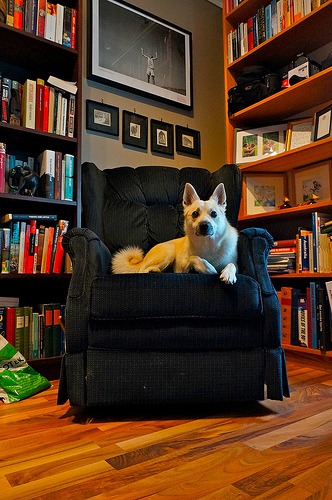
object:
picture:
[181, 134, 195, 151]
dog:
[110, 182, 238, 284]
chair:
[54, 161, 290, 417]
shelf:
[227, 67, 331, 123]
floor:
[0, 352, 331, 498]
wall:
[82, 0, 224, 172]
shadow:
[58, 402, 276, 428]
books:
[50, 302, 64, 359]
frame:
[84, 98, 120, 139]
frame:
[121, 109, 149, 153]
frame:
[149, 117, 174, 158]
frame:
[174, 122, 201, 160]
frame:
[86, 1, 195, 120]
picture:
[88, 0, 191, 109]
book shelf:
[0, 0, 87, 379]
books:
[314, 284, 332, 353]